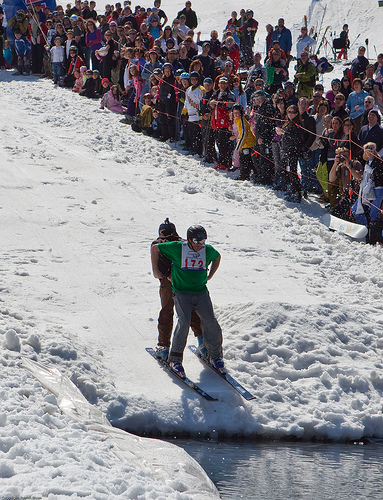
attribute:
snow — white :
[3, 4, 382, 498]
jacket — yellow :
[233, 117, 257, 150]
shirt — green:
[156, 240, 218, 294]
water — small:
[143, 419, 376, 493]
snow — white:
[1, 422, 112, 496]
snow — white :
[15, 141, 143, 296]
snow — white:
[2, 66, 381, 495]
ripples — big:
[223, 459, 366, 486]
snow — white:
[4, 74, 377, 446]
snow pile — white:
[214, 293, 373, 433]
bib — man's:
[179, 241, 206, 266]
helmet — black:
[177, 221, 209, 239]